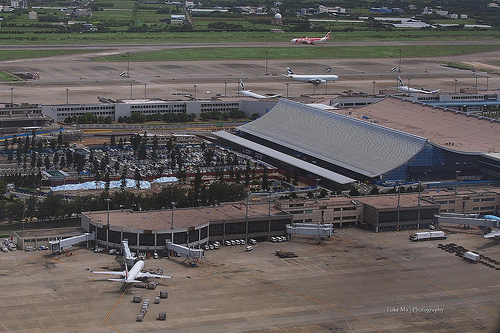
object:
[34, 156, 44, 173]
trees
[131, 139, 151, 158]
trees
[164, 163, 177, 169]
trees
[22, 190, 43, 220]
trees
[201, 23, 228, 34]
trees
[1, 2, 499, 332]
airport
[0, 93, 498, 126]
airport terminal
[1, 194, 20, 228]
trees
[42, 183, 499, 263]
airport terminal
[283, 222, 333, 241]
tunnel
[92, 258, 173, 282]
airplane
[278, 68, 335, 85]
white plane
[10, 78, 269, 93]
runway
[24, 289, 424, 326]
runway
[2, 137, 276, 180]
airport parking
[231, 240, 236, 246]
cars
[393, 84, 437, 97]
plane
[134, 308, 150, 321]
luggage car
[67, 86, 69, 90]
light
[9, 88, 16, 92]
light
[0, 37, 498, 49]
runway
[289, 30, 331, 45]
plane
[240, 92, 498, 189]
roof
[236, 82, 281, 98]
plane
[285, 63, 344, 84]
plane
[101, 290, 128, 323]
line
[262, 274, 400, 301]
ground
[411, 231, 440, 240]
truck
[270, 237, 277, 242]
cars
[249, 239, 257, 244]
cars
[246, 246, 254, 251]
cars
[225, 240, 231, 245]
cars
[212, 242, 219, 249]
cars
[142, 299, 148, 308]
luggage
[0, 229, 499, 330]
tarmac